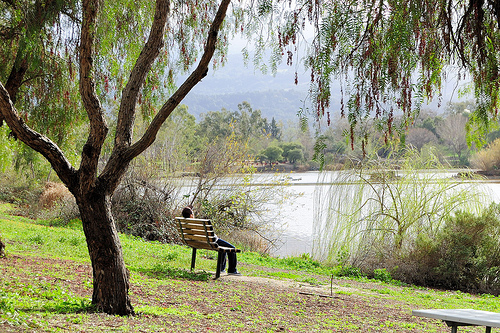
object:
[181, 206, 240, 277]
guy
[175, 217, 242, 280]
bench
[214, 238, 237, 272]
jeans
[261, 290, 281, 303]
patches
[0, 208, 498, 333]
ground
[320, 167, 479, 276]
water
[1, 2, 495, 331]
park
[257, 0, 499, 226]
trees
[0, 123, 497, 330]
background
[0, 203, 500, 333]
grass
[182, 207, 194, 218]
head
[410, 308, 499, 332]
bench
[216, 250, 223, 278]
leg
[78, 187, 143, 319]
tree trunk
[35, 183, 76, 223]
bush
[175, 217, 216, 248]
back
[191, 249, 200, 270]
leg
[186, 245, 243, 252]
seat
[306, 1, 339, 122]
branches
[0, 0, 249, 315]
tree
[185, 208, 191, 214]
hair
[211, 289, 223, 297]
grass sprouts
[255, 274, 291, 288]
dirt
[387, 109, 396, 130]
blossoms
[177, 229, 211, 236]
slats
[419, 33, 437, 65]
blooms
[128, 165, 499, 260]
water